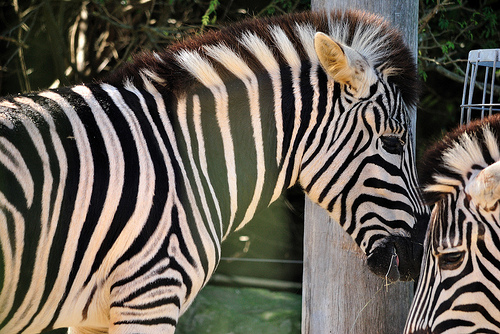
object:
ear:
[312, 28, 371, 99]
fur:
[332, 70, 346, 80]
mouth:
[379, 238, 413, 279]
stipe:
[237, 74, 270, 233]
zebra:
[400, 116, 500, 333]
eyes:
[378, 129, 408, 152]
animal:
[1, 7, 437, 333]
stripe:
[450, 301, 500, 328]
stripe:
[361, 174, 415, 205]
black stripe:
[117, 277, 182, 304]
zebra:
[2, 9, 447, 333]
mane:
[417, 113, 500, 206]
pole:
[300, 0, 418, 332]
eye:
[436, 246, 467, 270]